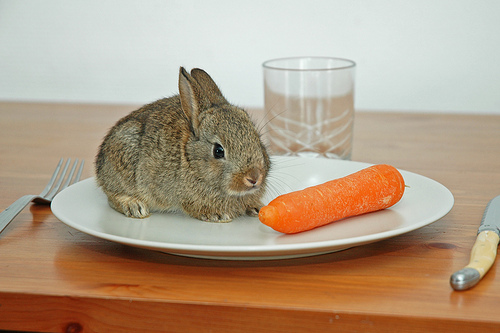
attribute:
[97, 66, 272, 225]
bunny — small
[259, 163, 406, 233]
carrot — orange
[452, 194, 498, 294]
knife — silver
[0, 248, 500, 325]
table — brown, wooden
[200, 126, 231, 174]
eye — black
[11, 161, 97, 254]
fork — silver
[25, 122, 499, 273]
plate — white, round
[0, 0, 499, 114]
wall — white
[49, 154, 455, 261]
plate — white, round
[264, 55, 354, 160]
glass — clear